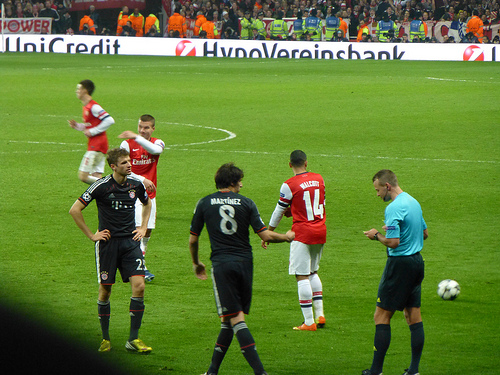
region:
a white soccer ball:
[432, 276, 463, 303]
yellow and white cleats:
[126, 339, 156, 359]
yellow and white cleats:
[99, 338, 113, 355]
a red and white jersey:
[266, 170, 334, 250]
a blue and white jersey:
[190, 183, 269, 266]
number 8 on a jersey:
[212, 198, 240, 245]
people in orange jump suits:
[74, 10, 221, 39]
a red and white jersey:
[121, 131, 168, 198]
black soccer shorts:
[370, 249, 427, 317]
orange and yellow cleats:
[295, 321, 319, 333]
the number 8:
[197, 201, 271, 269]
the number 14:
[286, 189, 353, 242]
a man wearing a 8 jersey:
[197, 135, 266, 295]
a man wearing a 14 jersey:
[262, 131, 351, 255]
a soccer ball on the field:
[429, 263, 492, 341]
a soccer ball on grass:
[430, 250, 485, 328]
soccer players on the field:
[65, 95, 483, 369]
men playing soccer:
[36, 85, 438, 356]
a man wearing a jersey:
[87, 146, 151, 263]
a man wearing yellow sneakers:
[59, 140, 200, 368]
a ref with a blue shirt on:
[364, 162, 437, 370]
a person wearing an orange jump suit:
[76, 6, 97, 31]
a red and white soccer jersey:
[265, 165, 330, 245]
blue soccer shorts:
[210, 253, 256, 323]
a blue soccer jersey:
[182, 183, 277, 263]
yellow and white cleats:
[96, 332, 111, 358]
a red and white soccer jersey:
[121, 125, 176, 200]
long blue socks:
[365, 311, 393, 370]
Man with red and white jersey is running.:
[65, 77, 115, 182]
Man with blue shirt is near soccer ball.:
[360, 167, 462, 374]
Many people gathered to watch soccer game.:
[2, 1, 499, 44]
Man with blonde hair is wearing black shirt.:
[68, 148, 151, 355]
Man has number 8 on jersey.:
[186, 163, 296, 373]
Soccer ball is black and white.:
[437, 278, 460, 301]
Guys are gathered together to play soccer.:
[2, 53, 495, 372]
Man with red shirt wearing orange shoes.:
[260, 148, 330, 332]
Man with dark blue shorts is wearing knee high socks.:
[359, 168, 431, 373]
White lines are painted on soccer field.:
[0, 53, 498, 373]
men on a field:
[46, 50, 491, 370]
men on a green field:
[52, 79, 443, 356]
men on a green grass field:
[80, 78, 496, 363]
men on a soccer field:
[21, 102, 483, 348]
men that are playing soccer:
[64, 79, 421, 374]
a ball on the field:
[416, 244, 498, 324]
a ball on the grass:
[407, 250, 497, 340]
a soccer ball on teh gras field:
[429, 261, 468, 315]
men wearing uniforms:
[18, 94, 424, 366]